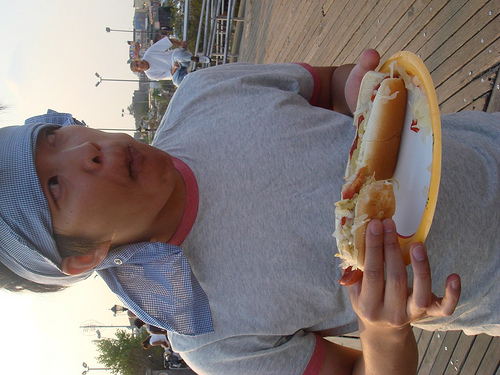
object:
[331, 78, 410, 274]
buns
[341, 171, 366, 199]
hot dog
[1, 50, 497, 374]
boy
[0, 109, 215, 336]
bandana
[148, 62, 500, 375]
shirt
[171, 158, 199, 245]
pink collar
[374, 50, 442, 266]
plate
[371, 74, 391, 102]
ketchup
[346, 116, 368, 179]
mustard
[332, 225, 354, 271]
onion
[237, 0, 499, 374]
deck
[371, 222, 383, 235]
nails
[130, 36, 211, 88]
man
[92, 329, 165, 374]
tree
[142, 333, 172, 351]
woman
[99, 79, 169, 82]
pole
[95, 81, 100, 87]
lights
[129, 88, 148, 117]
buildings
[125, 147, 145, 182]
mouth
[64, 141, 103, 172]
nose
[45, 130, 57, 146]
eye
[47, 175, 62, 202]
eye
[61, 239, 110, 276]
ear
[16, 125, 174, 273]
head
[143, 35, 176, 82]
shirt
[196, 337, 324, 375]
sleeves